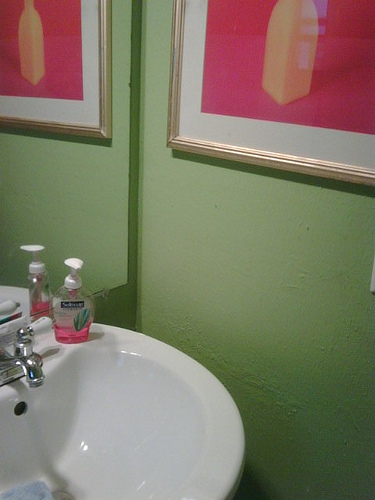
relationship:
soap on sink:
[50, 256, 95, 343] [6, 317, 248, 498]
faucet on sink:
[3, 305, 70, 397] [6, 317, 248, 498]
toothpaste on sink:
[1, 317, 23, 380] [6, 317, 248, 498]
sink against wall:
[6, 317, 248, 498] [1, 0, 372, 497]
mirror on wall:
[1, 0, 133, 327] [80, 3, 179, 334]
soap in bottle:
[52, 323, 90, 342] [50, 256, 93, 341]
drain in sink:
[23, 432, 192, 495] [6, 317, 248, 498]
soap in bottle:
[52, 323, 90, 342] [30, 252, 98, 343]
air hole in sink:
[12, 399, 30, 416] [6, 317, 248, 498]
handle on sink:
[16, 320, 36, 343] [20, 350, 219, 480]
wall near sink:
[177, 201, 312, 338] [25, 321, 243, 473]